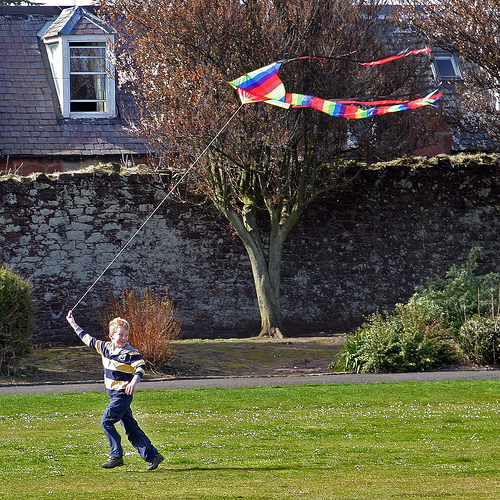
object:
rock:
[50, 250, 69, 260]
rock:
[95, 242, 118, 255]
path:
[0, 369, 498, 398]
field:
[0, 379, 499, 499]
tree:
[92, 0, 432, 342]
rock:
[73, 196, 91, 207]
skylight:
[429, 52, 463, 81]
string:
[71, 105, 243, 314]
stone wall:
[0, 151, 499, 340]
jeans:
[100, 390, 158, 462]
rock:
[66, 231, 85, 243]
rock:
[78, 215, 95, 223]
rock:
[96, 252, 116, 263]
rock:
[69, 207, 84, 215]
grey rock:
[66, 230, 86, 242]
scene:
[0, 0, 499, 499]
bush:
[456, 287, 498, 367]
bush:
[413, 247, 498, 322]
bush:
[326, 300, 465, 377]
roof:
[0, 4, 193, 162]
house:
[0, 0, 497, 161]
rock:
[49, 217, 73, 226]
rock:
[0, 212, 22, 233]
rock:
[139, 203, 155, 211]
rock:
[34, 266, 59, 277]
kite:
[223, 47, 443, 119]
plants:
[0, 242, 499, 410]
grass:
[3, 383, 500, 499]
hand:
[66, 310, 75, 324]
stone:
[115, 192, 252, 332]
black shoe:
[101, 456, 124, 469]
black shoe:
[147, 453, 164, 470]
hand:
[125, 382, 137, 395]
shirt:
[75, 326, 146, 395]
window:
[60, 35, 116, 118]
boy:
[64, 310, 164, 472]